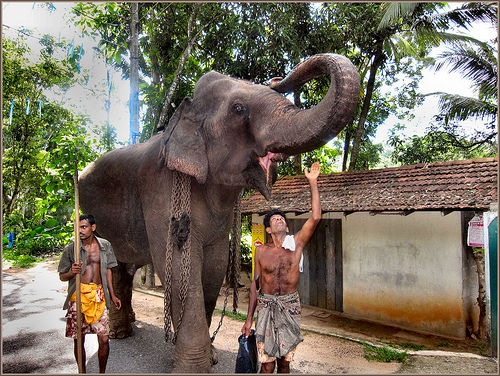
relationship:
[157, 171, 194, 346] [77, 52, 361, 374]
chain draped around elephant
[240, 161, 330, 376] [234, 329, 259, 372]
man carrying bag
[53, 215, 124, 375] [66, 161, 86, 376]
man holding pole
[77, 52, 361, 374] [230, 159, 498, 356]
elephant walking pass building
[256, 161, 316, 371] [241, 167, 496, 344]
man walking pass building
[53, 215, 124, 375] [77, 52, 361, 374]
man walking pass elephant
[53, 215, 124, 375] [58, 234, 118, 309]
man wearing green shirt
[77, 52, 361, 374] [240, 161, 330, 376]
elephant between man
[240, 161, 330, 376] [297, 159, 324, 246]
man raising arm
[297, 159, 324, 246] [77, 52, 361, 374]
arm toward elephant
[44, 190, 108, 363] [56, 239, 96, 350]
man looking to side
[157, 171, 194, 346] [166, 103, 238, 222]
chain looped around neck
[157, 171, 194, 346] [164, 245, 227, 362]
chain looped around leg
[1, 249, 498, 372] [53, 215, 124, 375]
path curving behind man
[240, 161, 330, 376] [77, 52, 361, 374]
man reaching elephant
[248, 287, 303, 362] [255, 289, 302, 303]
shirt tied around waist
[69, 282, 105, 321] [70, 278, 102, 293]
yellow material tied around waist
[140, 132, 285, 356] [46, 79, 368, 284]
chain hanging off elephant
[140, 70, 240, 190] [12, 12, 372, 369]
ear of elephant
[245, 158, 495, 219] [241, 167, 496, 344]
shingles on building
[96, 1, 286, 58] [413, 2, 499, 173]
top of tree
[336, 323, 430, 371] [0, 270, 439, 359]
weeds growing out of ground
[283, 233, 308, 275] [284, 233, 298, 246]
shirt on shoulder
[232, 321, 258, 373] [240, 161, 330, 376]
bag held by man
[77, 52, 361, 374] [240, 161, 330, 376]
elephant walks with man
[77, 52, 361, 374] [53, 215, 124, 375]
elephant walks with man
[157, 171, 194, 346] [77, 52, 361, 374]
chain around elephant